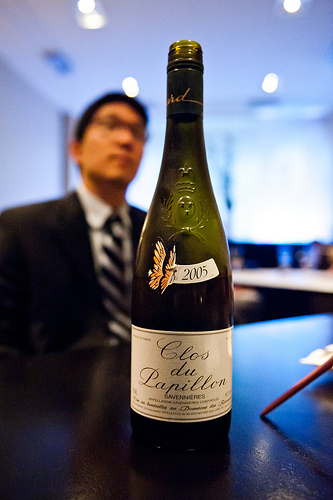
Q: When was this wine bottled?
A: 2005.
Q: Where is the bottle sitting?
A: On a table.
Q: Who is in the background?
A: A man.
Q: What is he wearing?
A: A suit and tie.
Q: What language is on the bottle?
A: French.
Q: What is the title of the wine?
A: Clos du Papillon.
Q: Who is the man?
A: A businessman.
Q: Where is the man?
A: Behind the desk.